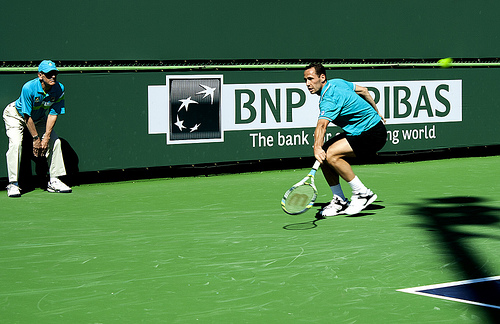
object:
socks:
[347, 175, 368, 196]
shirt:
[317, 78, 383, 137]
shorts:
[323, 118, 386, 156]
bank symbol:
[164, 73, 226, 145]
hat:
[36, 59, 61, 73]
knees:
[320, 144, 344, 164]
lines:
[395, 288, 498, 310]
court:
[0, 153, 499, 323]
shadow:
[390, 195, 499, 324]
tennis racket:
[279, 159, 322, 216]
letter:
[432, 82, 455, 118]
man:
[0, 59, 74, 197]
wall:
[0, 62, 499, 179]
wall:
[0, 0, 499, 62]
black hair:
[301, 62, 328, 80]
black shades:
[42, 69, 60, 79]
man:
[301, 63, 389, 216]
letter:
[232, 87, 257, 125]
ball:
[434, 56, 452, 69]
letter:
[412, 85, 437, 117]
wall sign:
[144, 73, 462, 146]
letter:
[260, 89, 280, 124]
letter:
[282, 87, 307, 123]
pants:
[0, 100, 67, 181]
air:
[0, 0, 499, 62]